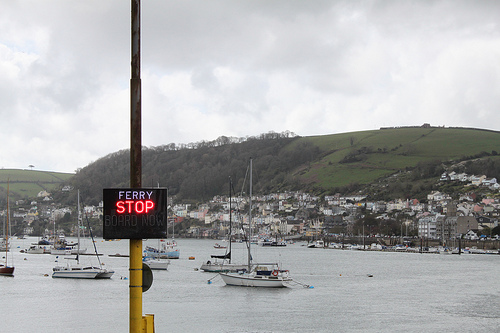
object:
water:
[3, 226, 499, 331]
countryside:
[61, 127, 499, 239]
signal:
[102, 188, 166, 241]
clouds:
[1, 1, 499, 174]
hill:
[0, 125, 499, 211]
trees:
[68, 131, 322, 206]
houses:
[441, 170, 499, 190]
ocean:
[1, 235, 499, 333]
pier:
[308, 245, 500, 258]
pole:
[129, 0, 143, 333]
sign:
[102, 187, 167, 239]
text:
[115, 190, 155, 213]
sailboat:
[208, 158, 313, 288]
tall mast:
[247, 157, 252, 272]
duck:
[367, 274, 373, 277]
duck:
[311, 273, 315, 275]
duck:
[43, 274, 49, 277]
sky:
[1, 1, 499, 174]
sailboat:
[52, 189, 114, 279]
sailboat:
[143, 183, 169, 269]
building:
[418, 201, 478, 240]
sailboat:
[1, 174, 16, 277]